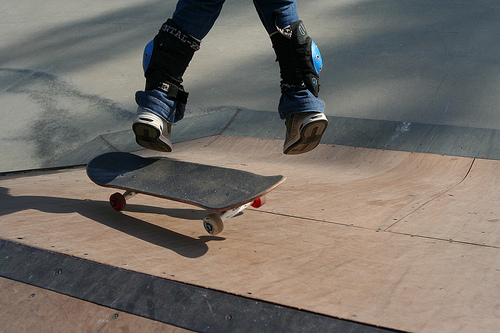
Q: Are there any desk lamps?
A: No, there are no desk lamps.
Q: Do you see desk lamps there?
A: No, there are no desk lamps.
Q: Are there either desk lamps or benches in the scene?
A: No, there are no desk lamps or benches.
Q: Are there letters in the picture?
A: Yes, there are letters.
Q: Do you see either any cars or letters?
A: Yes, there are letters.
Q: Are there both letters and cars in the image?
A: No, there are letters but no cars.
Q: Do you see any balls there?
A: No, there are no balls.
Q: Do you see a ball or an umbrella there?
A: No, there are no balls or umbrellas.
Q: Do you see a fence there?
A: No, there are no fences.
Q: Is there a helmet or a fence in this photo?
A: No, there are no fences or helmets.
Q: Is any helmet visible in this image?
A: No, there are no helmets.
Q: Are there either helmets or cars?
A: No, there are no helmets or cars.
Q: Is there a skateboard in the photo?
A: Yes, there is a skateboard.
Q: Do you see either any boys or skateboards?
A: Yes, there is a skateboard.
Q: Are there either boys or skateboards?
A: Yes, there is a skateboard.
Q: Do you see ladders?
A: No, there are no ladders.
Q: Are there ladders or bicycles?
A: No, there are no ladders or bicycles.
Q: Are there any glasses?
A: No, there are no glasses.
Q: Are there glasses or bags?
A: No, there are no glasses or bags.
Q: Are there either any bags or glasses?
A: No, there are no glasses or bags.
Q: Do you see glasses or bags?
A: No, there are no glasses or bags.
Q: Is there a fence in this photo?
A: No, there are no fences.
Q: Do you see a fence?
A: No, there are no fences.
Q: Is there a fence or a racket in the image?
A: No, there are no fences or rackets.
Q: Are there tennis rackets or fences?
A: No, there are no fences or tennis rackets.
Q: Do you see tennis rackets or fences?
A: No, there are no fences or tennis rackets.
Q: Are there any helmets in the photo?
A: No, there are no helmets.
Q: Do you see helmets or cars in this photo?
A: No, there are no helmets or cars.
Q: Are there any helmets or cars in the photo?
A: No, there are no helmets or cars.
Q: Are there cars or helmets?
A: No, there are no helmets or cars.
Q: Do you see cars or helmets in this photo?
A: No, there are no helmets or cars.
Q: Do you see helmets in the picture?
A: No, there are no helmets.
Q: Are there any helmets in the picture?
A: No, there are no helmets.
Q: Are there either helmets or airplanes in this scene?
A: No, there are no helmets or airplanes.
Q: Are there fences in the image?
A: No, there are no fences.